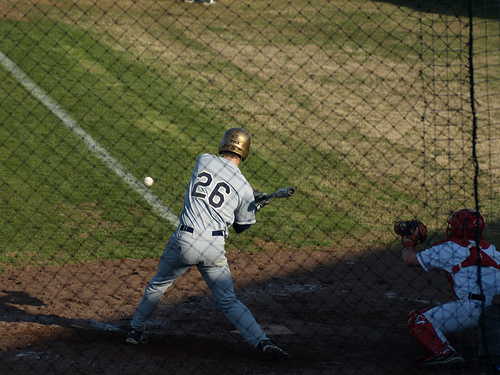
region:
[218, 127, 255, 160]
gold baseball helmet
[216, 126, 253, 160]
gold helmet on a baseball player's head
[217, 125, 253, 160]
helmet on a baseball player's head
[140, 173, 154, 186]
baseball in the air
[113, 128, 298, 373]
baseball headed towards a player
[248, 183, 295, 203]
black bat in a baseball player's hand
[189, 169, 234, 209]
number print on the back of a baseball jersey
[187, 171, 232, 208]
twenty six number print on a baseball jersey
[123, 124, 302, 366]
baseball player swinging his bat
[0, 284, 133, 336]
shadow on a ground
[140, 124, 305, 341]
man is holding bat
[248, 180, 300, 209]
man is swinging bat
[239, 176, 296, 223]
man will hit the ball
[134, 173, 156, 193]
ball is in the air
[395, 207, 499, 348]
catcher is behind the batter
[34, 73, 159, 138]
grass is green in color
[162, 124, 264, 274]
man is wearing a jersey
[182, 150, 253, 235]
jersay has number 26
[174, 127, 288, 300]
man is wearing helmet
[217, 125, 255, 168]
helmet is gold in color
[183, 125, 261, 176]
the head of a man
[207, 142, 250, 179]
the neck of a man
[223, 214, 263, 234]
the elbow of a man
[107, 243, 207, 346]
the leg of a man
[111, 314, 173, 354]
the foot of a man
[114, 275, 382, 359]
a man wearing shoes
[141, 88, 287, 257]
a man wearing a helmet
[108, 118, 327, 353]
a man wearing a uniform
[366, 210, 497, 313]
a man wearing a glove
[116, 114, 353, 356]
a man playing baseball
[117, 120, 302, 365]
the batter readies to hit the ball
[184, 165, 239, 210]
this ball player's jersey number is 26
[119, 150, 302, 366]
since the player is not wearing white, he is on the visiting team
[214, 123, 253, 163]
the batter is wearing a batting helmet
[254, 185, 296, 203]
the batter's bat is black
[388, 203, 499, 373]
the catcher readies to catch the pitch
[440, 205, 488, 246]
the catcher's mask protects his face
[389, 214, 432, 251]
the catcher wears his glove on his left hand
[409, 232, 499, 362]
since the catcher is wearing white, he is on the home team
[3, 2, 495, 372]
there is a protective netting behind the batter to protect spectators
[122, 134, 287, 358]
A person is playing.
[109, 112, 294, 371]
A person is standing up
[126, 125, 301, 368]
the batter is caught in mid swing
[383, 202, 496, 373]
the catcher prepares to catch the ball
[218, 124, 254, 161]
the batter is wearing a gold helmet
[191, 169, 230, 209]
the player at bat is number 26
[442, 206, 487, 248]
the catcher is wearing a red mask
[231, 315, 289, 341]
this is home plate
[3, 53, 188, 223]
the right fowl line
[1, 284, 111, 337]
a shadow cast by the batter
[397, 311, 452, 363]
the catcher's shin pad is red